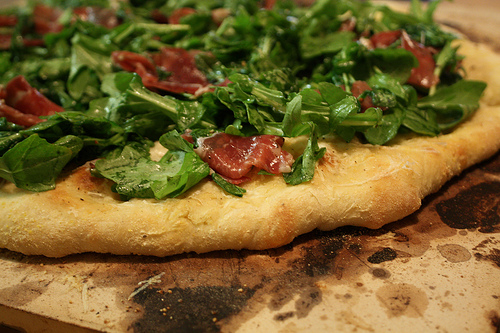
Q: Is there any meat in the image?
A: Yes, there is meat.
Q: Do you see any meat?
A: Yes, there is meat.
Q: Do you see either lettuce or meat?
A: Yes, there is meat.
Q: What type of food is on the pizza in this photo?
A: The food is meat.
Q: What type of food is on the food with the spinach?
A: The food is meat.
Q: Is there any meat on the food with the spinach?
A: Yes, there is meat on the pizza.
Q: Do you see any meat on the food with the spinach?
A: Yes, there is meat on the pizza.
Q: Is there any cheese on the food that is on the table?
A: No, there is meat on the pizza.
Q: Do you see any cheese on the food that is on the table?
A: No, there is meat on the pizza.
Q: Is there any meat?
A: Yes, there is meat.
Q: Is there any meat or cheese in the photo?
A: Yes, there is meat.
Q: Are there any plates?
A: No, there are no plates.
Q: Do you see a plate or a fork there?
A: No, there are no plates or forks.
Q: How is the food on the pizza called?
A: The food is meat.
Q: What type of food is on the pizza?
A: The food is meat.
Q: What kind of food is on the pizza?
A: The food is meat.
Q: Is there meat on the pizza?
A: Yes, there is meat on the pizza.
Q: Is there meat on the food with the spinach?
A: Yes, there is meat on the pizza.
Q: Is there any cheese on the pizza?
A: No, there is meat on the pizza.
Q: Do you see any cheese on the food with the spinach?
A: No, there is meat on the pizza.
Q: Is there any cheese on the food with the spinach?
A: No, there is meat on the pizza.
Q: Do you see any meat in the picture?
A: Yes, there is meat.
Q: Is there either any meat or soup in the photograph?
A: Yes, there is meat.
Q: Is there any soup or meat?
A: Yes, there is meat.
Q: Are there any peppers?
A: No, there are no peppers.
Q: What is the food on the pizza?
A: The food is meat.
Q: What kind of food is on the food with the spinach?
A: The food is meat.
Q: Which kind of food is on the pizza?
A: The food is meat.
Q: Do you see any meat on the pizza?
A: Yes, there is meat on the pizza.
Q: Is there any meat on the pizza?
A: Yes, there is meat on the pizza.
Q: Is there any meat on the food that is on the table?
A: Yes, there is meat on the pizza.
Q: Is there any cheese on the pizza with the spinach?
A: No, there is meat on the pizza.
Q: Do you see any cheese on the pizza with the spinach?
A: No, there is meat on the pizza.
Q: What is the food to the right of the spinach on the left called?
A: The food is meat.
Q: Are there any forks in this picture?
A: No, there are no forks.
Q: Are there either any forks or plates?
A: No, there are no forks or plates.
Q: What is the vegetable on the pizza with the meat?
A: The vegetable is spinach.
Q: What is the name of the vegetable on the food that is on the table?
A: The vegetable is spinach.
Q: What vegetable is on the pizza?
A: The vegetable is spinach.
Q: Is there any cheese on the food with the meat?
A: No, there is spinach on the pizza.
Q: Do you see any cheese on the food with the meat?
A: No, there is spinach on the pizza.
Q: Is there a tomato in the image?
A: No, there are no tomatoes.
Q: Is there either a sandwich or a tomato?
A: No, there are no tomatoes or sandwiches.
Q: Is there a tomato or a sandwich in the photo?
A: No, there are no tomatoes or sandwiches.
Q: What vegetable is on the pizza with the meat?
A: The vegetable is spinach.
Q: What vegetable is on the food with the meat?
A: The vegetable is spinach.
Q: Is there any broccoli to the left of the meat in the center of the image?
A: No, there is spinach to the left of the meat.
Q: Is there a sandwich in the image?
A: No, there are no sandwiches.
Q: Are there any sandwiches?
A: No, there are no sandwiches.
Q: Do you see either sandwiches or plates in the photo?
A: No, there are no sandwiches or plates.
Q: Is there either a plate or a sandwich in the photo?
A: No, there are no sandwiches or plates.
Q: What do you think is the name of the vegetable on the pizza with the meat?
A: The vegetable is spinach.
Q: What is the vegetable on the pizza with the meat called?
A: The vegetable is spinach.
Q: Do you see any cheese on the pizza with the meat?
A: No, there is spinach on the pizza.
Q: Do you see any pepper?
A: No, there are no peppers.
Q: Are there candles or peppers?
A: No, there are no peppers or candles.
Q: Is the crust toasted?
A: Yes, the crust is toasted.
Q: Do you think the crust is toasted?
A: Yes, the crust is toasted.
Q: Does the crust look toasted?
A: Yes, the crust is toasted.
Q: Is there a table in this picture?
A: Yes, there is a table.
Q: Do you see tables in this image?
A: Yes, there is a table.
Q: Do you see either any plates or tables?
A: Yes, there is a table.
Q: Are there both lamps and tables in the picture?
A: No, there is a table but no lamps.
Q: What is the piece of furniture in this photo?
A: The piece of furniture is a table.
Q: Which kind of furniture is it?
A: The piece of furniture is a table.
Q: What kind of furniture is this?
A: This is a table.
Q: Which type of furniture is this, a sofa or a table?
A: This is a table.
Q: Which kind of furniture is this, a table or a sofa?
A: This is a table.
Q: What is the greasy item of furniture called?
A: The piece of furniture is a table.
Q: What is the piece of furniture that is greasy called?
A: The piece of furniture is a table.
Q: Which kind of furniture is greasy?
A: The furniture is a table.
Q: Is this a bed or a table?
A: This is a table.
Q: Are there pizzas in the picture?
A: Yes, there is a pizza.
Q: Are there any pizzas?
A: Yes, there is a pizza.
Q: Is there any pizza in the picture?
A: Yes, there is a pizza.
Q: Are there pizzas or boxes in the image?
A: Yes, there is a pizza.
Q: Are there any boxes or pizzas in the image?
A: Yes, there is a pizza.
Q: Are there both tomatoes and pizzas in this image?
A: No, there is a pizza but no tomatoes.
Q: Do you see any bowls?
A: No, there are no bowls.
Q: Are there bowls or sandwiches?
A: No, there are no bowls or sandwiches.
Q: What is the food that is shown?
A: The food is a pizza.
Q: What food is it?
A: The food is a pizza.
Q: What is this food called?
A: This is a pizza.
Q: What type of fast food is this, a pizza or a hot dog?
A: This is a pizza.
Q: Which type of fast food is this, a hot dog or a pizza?
A: This is a pizza.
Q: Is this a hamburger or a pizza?
A: This is a pizza.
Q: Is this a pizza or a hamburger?
A: This is a pizza.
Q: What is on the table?
A: The pizza is on the table.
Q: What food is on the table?
A: The food is a pizza.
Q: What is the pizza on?
A: The pizza is on the table.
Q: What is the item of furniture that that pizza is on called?
A: The piece of furniture is a table.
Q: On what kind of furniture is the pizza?
A: The pizza is on the table.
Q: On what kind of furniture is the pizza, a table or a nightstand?
A: The pizza is on a table.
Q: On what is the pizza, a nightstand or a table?
A: The pizza is on a table.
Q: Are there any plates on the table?
A: No, there is a pizza on the table.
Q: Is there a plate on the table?
A: No, there is a pizza on the table.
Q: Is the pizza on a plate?
A: No, the pizza is on the table.